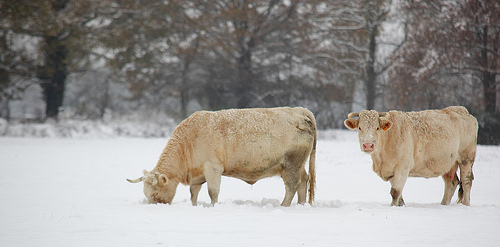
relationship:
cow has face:
[134, 105, 321, 211] [137, 169, 179, 208]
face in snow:
[137, 169, 179, 208] [1, 137, 497, 247]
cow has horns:
[134, 105, 321, 211] [122, 171, 168, 185]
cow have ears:
[129, 105, 322, 211] [342, 117, 395, 130]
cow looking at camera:
[352, 106, 478, 210] [7, 7, 495, 238]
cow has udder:
[352, 106, 478, 210] [442, 161, 459, 183]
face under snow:
[137, 169, 179, 208] [1, 137, 497, 247]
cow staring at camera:
[352, 106, 478, 210] [7, 7, 495, 238]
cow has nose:
[352, 106, 478, 210] [359, 142, 378, 153]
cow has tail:
[134, 105, 321, 211] [306, 112, 319, 207]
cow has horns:
[352, 106, 478, 210] [346, 110, 393, 120]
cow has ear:
[134, 105, 321, 211] [159, 175, 171, 187]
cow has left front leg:
[134, 105, 321, 211] [200, 156, 226, 209]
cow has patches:
[352, 106, 478, 210] [453, 153, 477, 186]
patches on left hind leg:
[453, 153, 477, 186] [454, 146, 478, 213]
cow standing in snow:
[134, 105, 321, 211] [1, 137, 497, 247]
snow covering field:
[1, 137, 497, 247] [2, 97, 498, 246]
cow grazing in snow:
[134, 105, 321, 211] [1, 137, 497, 247]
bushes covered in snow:
[1, 119, 171, 141] [1, 137, 497, 247]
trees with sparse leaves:
[1, 4, 493, 112] [18, 9, 480, 66]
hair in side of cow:
[169, 121, 288, 163] [134, 105, 321, 211]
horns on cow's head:
[122, 171, 168, 185] [124, 167, 178, 205]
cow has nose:
[134, 105, 321, 211] [359, 142, 378, 153]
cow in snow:
[129, 105, 322, 211] [1, 137, 497, 247]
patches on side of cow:
[453, 153, 477, 186] [352, 106, 478, 210]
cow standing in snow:
[129, 105, 322, 211] [1, 137, 497, 247]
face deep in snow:
[137, 169, 179, 208] [1, 137, 497, 247]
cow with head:
[352, 106, 478, 210] [347, 106, 392, 156]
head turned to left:
[347, 106, 392, 156] [337, 94, 452, 240]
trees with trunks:
[1, 4, 493, 112] [37, 51, 66, 118]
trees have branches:
[1, 4, 493, 112] [69, 19, 180, 112]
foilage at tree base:
[58, 112, 177, 128] [1, 106, 199, 127]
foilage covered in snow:
[58, 112, 177, 128] [1, 137, 497, 247]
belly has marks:
[225, 137, 314, 203] [235, 157, 308, 183]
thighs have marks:
[283, 148, 307, 177] [235, 157, 308, 183]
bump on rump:
[276, 103, 308, 118] [282, 103, 320, 156]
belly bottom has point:
[421, 146, 463, 176] [449, 150, 457, 160]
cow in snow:
[134, 105, 321, 211] [1, 137, 497, 247]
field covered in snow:
[2, 97, 498, 246] [1, 137, 497, 247]